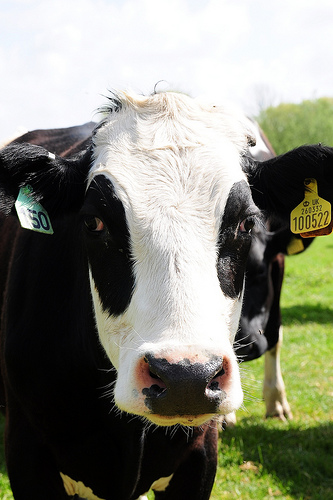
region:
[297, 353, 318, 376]
Small patch of green grass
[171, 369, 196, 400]
Black nose of the cow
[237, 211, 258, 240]
Left eye of the cow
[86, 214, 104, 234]
Right eye of the cow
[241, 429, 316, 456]
Shadow of the cow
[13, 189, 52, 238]
Teal and dark blue tag on the cow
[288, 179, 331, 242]
Yellow and black tag on cow's left ear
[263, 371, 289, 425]
Foot of the second cow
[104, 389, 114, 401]
White hairs of cow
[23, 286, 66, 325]
Black skin of the cow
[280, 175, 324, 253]
Yellow tag in a cows ear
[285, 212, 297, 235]
Black number on a yellow tag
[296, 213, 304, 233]
Black number on a yellow tag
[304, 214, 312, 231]
Black number on a yellow tag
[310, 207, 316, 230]
Black number on a yellow tag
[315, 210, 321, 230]
Black number on a yellow tag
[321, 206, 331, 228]
Black number on a yellow tag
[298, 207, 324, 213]
Black number on a yellow tag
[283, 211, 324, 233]
Black number on a yellow tag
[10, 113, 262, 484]
Black and white dairy cow in a field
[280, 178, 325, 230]
The cow has yellow tag on ear.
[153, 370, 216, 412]
The nose of the cow is black.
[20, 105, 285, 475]
The cow is standing in grass.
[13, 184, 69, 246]
blue tag in the car right ear.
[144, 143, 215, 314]
Front of cow face is white.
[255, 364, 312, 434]
Cow feet on the grass.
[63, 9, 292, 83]
Clouds in the sky.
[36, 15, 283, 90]
The sky is clear.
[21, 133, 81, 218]
The cow has black ear.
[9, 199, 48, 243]
The number "150" on the tag.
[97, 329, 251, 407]
this is a nose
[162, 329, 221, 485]
the nose is black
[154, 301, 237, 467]
the nose is pink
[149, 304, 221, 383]
this is a face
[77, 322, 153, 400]
this is a cow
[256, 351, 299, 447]
this is a foot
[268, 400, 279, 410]
this is a hoof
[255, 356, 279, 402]
this is a leg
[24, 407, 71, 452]
the cow is large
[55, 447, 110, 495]
the cow is black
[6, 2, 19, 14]
blue patch of sky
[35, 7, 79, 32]
white cloud in the sky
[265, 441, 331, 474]
shadow of the cow on the ground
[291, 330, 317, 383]
green grass covering the ground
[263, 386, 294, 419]
front hoof of cow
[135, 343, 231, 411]
nostrils for cow to breathe from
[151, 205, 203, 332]
white fur on cow's head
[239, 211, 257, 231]
eyeball of cow for seeing through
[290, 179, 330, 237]
yellow tag with number on cow's ear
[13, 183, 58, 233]
blue tag with number on cow's ear